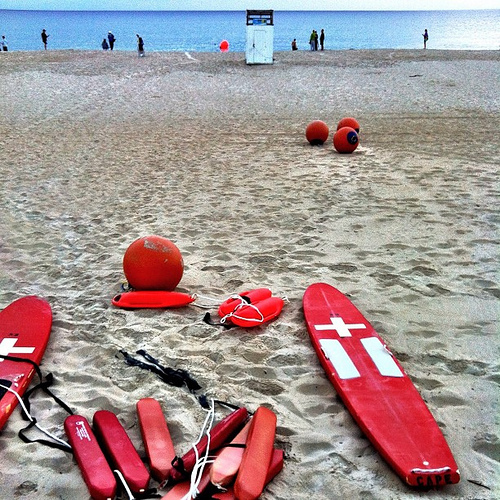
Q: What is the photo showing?
A: It is showing a beach.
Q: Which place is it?
A: It is a beach.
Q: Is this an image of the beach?
A: Yes, it is showing the beach.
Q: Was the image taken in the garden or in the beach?
A: It was taken at the beach.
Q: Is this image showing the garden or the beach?
A: It is showing the beach.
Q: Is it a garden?
A: No, it is a beach.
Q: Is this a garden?
A: No, it is a beach.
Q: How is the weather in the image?
A: It is clear.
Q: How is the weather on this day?
A: It is clear.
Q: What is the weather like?
A: It is clear.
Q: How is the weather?
A: It is clear.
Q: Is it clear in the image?
A: Yes, it is clear.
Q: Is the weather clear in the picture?
A: Yes, it is clear.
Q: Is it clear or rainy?
A: It is clear.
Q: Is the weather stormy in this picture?
A: No, it is clear.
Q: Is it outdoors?
A: Yes, it is outdoors.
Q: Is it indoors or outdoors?
A: It is outdoors.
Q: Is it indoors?
A: No, it is outdoors.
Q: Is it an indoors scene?
A: No, it is outdoors.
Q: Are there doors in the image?
A: Yes, there is a door.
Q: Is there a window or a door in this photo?
A: Yes, there is a door.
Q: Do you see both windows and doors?
A: No, there is a door but no windows.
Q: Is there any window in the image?
A: No, there are no windows.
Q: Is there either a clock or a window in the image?
A: No, there are no windows or clocks.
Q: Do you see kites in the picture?
A: No, there are no kites.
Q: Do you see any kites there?
A: No, there are no kites.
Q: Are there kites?
A: No, there are no kites.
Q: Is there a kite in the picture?
A: No, there are no kites.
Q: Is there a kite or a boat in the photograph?
A: No, there are no kites or boats.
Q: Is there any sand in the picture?
A: Yes, there is sand.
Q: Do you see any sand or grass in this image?
A: Yes, there is sand.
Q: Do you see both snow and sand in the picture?
A: No, there is sand but no snow.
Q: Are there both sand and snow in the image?
A: No, there is sand but no snow.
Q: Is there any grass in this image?
A: No, there is no grass.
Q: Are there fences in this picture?
A: No, there are no fences.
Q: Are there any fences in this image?
A: No, there are no fences.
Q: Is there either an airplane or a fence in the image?
A: No, there are no fences or airplanes.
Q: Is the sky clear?
A: Yes, the sky is clear.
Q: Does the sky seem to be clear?
A: Yes, the sky is clear.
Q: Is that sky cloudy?
A: No, the sky is clear.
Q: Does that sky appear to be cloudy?
A: No, the sky is clear.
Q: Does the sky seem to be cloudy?
A: No, the sky is clear.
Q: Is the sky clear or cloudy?
A: The sky is clear.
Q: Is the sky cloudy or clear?
A: The sky is clear.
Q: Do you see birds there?
A: No, there are no birds.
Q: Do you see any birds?
A: No, there are no birds.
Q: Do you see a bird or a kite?
A: No, there are no birds or kites.